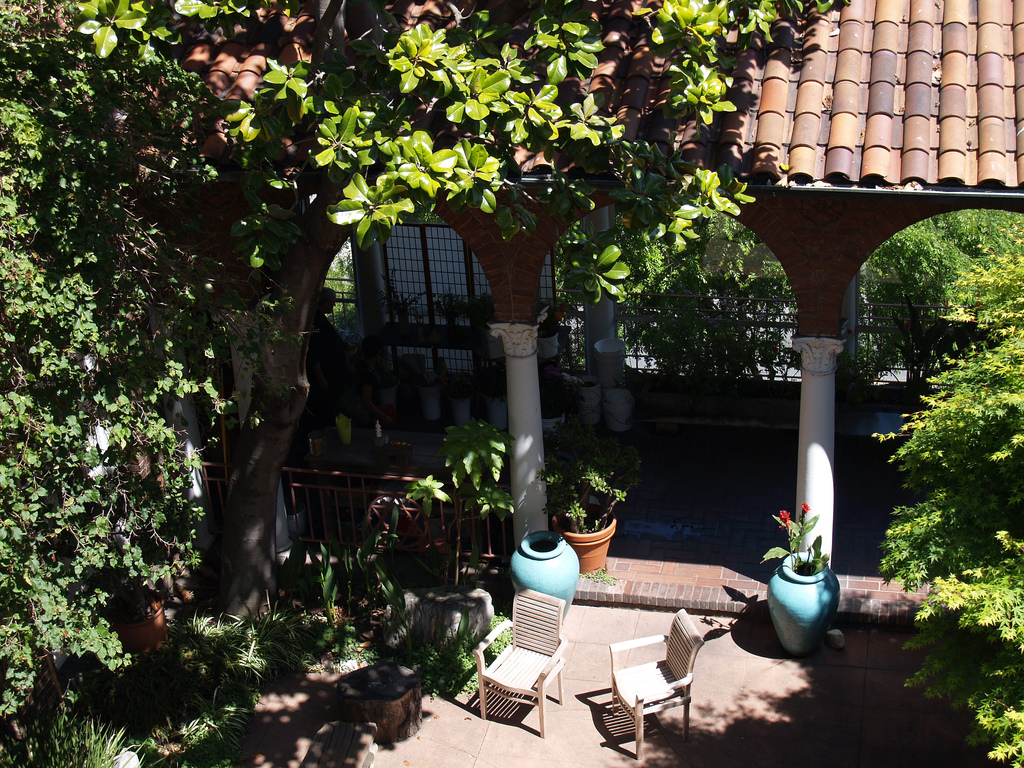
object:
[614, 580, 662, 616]
step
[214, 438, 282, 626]
trunk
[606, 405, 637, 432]
purse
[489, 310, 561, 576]
column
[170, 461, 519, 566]
railing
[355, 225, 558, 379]
window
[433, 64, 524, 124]
green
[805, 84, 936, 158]
surface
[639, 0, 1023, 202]
roof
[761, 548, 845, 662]
planter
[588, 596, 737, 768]
light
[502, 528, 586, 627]
planter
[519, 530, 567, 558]
empty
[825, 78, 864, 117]
tile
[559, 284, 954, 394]
fence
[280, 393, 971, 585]
porch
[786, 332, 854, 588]
column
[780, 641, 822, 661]
base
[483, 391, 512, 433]
pots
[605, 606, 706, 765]
chair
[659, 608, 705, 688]
back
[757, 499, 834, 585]
flowers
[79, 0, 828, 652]
tree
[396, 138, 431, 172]
leaves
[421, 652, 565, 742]
shadow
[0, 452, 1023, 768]
ground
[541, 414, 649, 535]
shrub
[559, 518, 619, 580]
planter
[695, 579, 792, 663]
shadow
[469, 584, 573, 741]
chair